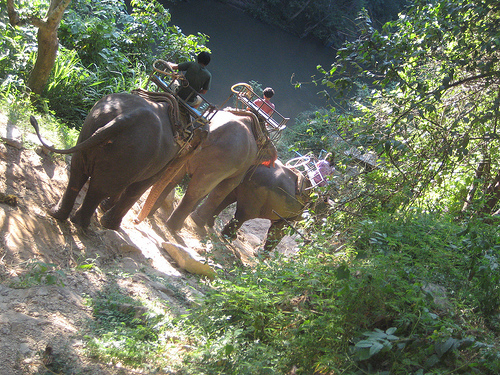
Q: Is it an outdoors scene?
A: Yes, it is outdoors.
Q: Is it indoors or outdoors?
A: It is outdoors.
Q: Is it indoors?
A: No, it is outdoors.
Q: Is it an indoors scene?
A: No, it is outdoors.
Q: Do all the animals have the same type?
A: Yes, all the animals are elephants.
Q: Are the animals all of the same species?
A: Yes, all the animals are elephants.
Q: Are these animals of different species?
A: No, all the animals are elephants.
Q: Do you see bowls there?
A: No, there are no bowls.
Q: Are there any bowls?
A: No, there are no bowls.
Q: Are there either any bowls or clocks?
A: No, there are no bowls or clocks.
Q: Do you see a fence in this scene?
A: No, there are no fences.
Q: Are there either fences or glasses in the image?
A: No, there are no fences or glasses.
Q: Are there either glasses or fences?
A: No, there are no fences or glasses.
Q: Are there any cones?
A: No, there are no cones.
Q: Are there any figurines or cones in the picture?
A: No, there are no cones or figurines.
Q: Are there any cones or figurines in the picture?
A: No, there are no cones or figurines.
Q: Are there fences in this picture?
A: No, there are no fences.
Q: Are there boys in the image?
A: No, there are no boys.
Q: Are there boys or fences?
A: No, there are no boys or fences.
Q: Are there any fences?
A: No, there are no fences.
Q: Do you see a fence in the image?
A: No, there are no fences.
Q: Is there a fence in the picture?
A: No, there are no fences.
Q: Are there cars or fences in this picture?
A: No, there are no fences or cars.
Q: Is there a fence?
A: No, there are no fences.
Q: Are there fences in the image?
A: No, there are no fences.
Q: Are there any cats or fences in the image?
A: No, there are no fences or cats.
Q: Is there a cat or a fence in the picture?
A: No, there are no fences or cats.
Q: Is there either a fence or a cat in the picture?
A: No, there are no fences or cats.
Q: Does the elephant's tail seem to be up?
A: Yes, the tail is up.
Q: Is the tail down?
A: No, the tail is up.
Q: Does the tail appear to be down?
A: No, the tail is up.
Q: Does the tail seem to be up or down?
A: The tail is up.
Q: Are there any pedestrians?
A: No, there are no pedestrians.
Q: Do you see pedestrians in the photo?
A: No, there are no pedestrians.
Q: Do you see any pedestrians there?
A: No, there are no pedestrians.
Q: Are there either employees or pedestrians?
A: No, there are no pedestrians or employees.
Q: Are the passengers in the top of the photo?
A: Yes, the passengers are in the top of the image.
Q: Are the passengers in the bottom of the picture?
A: No, the passengers are in the top of the image.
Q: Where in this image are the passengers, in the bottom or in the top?
A: The passengers are in the top of the image.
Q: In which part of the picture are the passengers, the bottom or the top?
A: The passengers are in the top of the image.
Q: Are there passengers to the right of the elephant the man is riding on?
A: Yes, there are passengers to the right of the elephant.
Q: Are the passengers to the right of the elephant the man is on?
A: Yes, the passengers are to the right of the elephant.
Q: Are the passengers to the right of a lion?
A: No, the passengers are to the right of the elephant.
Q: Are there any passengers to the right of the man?
A: Yes, there are passengers to the right of the man.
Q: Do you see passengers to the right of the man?
A: Yes, there are passengers to the right of the man.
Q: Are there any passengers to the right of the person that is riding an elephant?
A: Yes, there are passengers to the right of the man.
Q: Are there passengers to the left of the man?
A: No, the passengers are to the right of the man.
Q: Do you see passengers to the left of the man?
A: No, the passengers are to the right of the man.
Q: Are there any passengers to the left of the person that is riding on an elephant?
A: No, the passengers are to the right of the man.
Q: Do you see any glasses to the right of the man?
A: No, there are passengers to the right of the man.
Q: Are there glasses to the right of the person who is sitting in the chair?
A: No, there are passengers to the right of the man.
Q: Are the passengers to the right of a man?
A: Yes, the passengers are to the right of a man.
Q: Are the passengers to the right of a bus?
A: No, the passengers are to the right of a man.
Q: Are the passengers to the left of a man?
A: No, the passengers are to the right of a man.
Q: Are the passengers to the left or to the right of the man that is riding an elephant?
A: The passengers are to the right of the man.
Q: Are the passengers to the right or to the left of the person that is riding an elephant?
A: The passengers are to the right of the man.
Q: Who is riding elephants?
A: The passengers are riding elephants.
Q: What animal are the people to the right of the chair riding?
A: The passengers are riding elephants.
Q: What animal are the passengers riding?
A: The passengers are riding elephants.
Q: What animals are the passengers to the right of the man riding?
A: The passengers are riding elephants.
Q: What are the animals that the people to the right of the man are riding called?
A: The animals are elephants.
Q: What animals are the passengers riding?
A: The passengers are riding elephants.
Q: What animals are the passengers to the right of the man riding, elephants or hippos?
A: The passengers are riding elephants.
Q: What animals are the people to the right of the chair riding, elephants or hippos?
A: The passengers are riding elephants.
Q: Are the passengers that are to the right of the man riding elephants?
A: Yes, the passengers are riding elephants.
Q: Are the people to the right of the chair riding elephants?
A: Yes, the passengers are riding elephants.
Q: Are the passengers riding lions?
A: No, the passengers are riding elephants.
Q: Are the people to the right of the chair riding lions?
A: No, the passengers are riding elephants.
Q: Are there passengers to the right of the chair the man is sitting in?
A: Yes, there are passengers to the right of the chair.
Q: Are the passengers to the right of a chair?
A: Yes, the passengers are to the right of a chair.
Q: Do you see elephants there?
A: Yes, there are elephants.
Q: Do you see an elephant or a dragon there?
A: Yes, there are elephants.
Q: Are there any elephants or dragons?
A: Yes, there are elephants.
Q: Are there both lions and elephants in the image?
A: No, there are elephants but no lions.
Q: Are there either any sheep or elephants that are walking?
A: Yes, the elephants are walking.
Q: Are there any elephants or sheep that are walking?
A: Yes, the elephants are walking.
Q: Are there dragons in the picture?
A: No, there are no dragons.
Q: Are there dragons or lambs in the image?
A: No, there are no dragons or lambs.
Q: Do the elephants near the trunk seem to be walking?
A: Yes, the elephants are walking.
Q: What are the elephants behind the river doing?
A: The elephants are walking.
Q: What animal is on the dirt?
A: The elephants are on the dirt.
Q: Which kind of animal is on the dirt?
A: The animals are elephants.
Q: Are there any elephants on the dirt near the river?
A: Yes, there are elephants on the dirt.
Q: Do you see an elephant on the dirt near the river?
A: Yes, there are elephants on the dirt.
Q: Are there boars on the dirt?
A: No, there are elephants on the dirt.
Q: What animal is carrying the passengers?
A: The elephants are carrying the passengers.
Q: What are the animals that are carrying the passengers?
A: The animals are elephants.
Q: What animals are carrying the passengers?
A: The animals are elephants.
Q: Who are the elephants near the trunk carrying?
A: The elephants are carrying passengers.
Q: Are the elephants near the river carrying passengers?
A: Yes, the elephants are carrying passengers.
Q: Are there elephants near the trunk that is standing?
A: Yes, there are elephants near the trunk.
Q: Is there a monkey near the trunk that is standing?
A: No, there are elephants near the trunk.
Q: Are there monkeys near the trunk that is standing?
A: No, there are elephants near the trunk.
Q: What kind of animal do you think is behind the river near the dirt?
A: The animals are elephants.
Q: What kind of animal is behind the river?
A: The animals are elephants.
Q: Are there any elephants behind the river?
A: Yes, there are elephants behind the river.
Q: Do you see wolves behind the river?
A: No, there are elephants behind the river.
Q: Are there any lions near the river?
A: No, there are elephants near the river.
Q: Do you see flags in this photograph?
A: No, there are no flags.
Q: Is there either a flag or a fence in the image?
A: No, there are no flags or fences.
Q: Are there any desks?
A: No, there are no desks.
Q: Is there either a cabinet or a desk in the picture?
A: No, there are no desks or cabinets.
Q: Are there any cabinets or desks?
A: No, there are no desks or cabinets.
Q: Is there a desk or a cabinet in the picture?
A: No, there are no desks or cabinets.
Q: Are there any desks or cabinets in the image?
A: No, there are no desks or cabinets.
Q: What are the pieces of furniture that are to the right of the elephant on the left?
A: The pieces of furniture are chairs.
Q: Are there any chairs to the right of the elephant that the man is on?
A: Yes, there are chairs to the right of the elephant.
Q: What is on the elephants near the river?
A: The chairs are on the elephants.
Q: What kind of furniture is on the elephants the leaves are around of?
A: The pieces of furniture are chairs.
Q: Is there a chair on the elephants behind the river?
A: Yes, there are chairs on the elephants.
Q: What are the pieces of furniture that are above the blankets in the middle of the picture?
A: The pieces of furniture are chairs.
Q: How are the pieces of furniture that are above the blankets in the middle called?
A: The pieces of furniture are chairs.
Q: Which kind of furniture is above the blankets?
A: The pieces of furniture are chairs.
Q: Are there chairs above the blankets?
A: Yes, there are chairs above the blankets.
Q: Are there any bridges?
A: No, there are no bridges.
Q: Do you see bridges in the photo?
A: No, there are no bridges.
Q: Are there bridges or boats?
A: No, there are no bridges or boats.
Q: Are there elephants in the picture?
A: Yes, there is an elephant.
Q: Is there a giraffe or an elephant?
A: Yes, there is an elephant.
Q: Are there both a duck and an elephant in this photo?
A: No, there is an elephant but no ducks.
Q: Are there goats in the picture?
A: No, there are no goats.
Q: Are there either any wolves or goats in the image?
A: No, there are no goats or wolves.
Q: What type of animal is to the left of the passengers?
A: The animal is an elephant.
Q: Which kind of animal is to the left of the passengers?
A: The animal is an elephant.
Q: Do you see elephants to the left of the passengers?
A: Yes, there is an elephant to the left of the passengers.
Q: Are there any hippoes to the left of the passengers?
A: No, there is an elephant to the left of the passengers.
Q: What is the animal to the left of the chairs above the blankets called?
A: The animal is an elephant.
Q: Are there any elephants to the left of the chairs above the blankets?
A: Yes, there is an elephant to the left of the chairs.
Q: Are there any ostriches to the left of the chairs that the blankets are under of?
A: No, there is an elephant to the left of the chairs.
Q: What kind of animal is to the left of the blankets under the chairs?
A: The animal is an elephant.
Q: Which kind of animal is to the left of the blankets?
A: The animal is an elephant.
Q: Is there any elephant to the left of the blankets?
A: Yes, there is an elephant to the left of the blankets.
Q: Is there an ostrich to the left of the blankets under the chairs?
A: No, there is an elephant to the left of the blankets.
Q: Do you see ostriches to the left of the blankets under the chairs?
A: No, there is an elephant to the left of the blankets.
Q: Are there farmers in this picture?
A: No, there are no farmers.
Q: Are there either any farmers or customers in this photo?
A: No, there are no farmers or customers.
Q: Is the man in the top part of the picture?
A: Yes, the man is in the top of the image.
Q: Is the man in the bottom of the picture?
A: No, the man is in the top of the image.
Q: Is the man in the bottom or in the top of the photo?
A: The man is in the top of the image.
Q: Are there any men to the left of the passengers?
A: Yes, there is a man to the left of the passengers.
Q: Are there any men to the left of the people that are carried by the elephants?
A: Yes, there is a man to the left of the passengers.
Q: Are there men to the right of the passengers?
A: No, the man is to the left of the passengers.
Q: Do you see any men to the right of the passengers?
A: No, the man is to the left of the passengers.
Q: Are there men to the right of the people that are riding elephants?
A: No, the man is to the left of the passengers.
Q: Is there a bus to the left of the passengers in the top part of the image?
A: No, there is a man to the left of the passengers.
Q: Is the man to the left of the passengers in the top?
A: Yes, the man is to the left of the passengers.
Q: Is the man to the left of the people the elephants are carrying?
A: Yes, the man is to the left of the passengers.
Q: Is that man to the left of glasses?
A: No, the man is to the left of the passengers.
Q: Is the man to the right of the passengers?
A: No, the man is to the left of the passengers.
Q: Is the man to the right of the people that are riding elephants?
A: No, the man is to the left of the passengers.